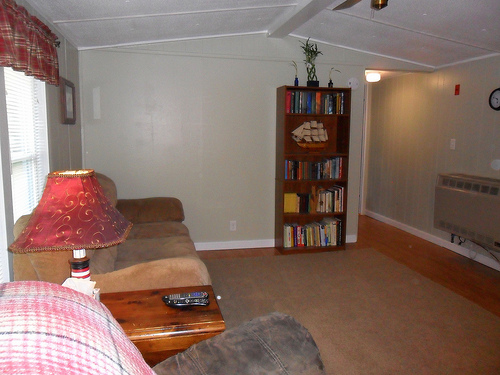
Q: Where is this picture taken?
A: A living room.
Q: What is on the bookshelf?
A: Books.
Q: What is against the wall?
A: A radiator.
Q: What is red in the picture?
A: A lampshade.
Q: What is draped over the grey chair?
A: A plaid blanket.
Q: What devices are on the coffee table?
A: Remote controls.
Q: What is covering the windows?
A: Blinds.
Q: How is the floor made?
A: Of wood.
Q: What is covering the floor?
A: A rug.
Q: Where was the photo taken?
A: In a living room.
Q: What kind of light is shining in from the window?
A: Sunlight.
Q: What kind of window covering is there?
A: Blinds.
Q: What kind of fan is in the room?
A: A ceiling fan.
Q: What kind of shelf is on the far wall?
A: A bookshelf.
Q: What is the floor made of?
A: Wood.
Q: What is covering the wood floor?
A: A rug.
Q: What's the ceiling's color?
A: White.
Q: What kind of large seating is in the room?
A: A couch.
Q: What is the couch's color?
A: Tan.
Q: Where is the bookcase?
A: Against the wall.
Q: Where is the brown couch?
A: Under the window.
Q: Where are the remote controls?
A: On the wooden table.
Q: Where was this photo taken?
A: In a living room.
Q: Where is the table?
A: Between the couch and the chair.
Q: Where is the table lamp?
A: Between the chair and the sofa.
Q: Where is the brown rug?
A: On the living room floor.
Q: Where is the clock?
A: Hanging on the wall.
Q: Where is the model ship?
A: On the bookshelf.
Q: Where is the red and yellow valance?
A: Above the window.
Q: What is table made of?
A: Wood.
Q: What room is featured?
A: Living room.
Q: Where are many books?
A: On a bookshelf.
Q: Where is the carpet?
A: On the floor.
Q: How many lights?
A: 1.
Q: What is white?
A: The ceiling.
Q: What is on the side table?
A: Lamp.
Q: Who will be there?
A: People.